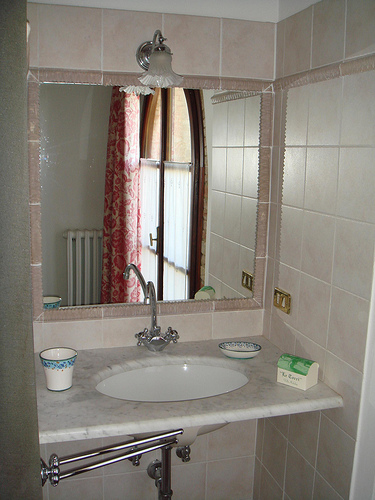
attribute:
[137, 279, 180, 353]
faucet — over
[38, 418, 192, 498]
pipes — silver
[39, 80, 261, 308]
mirror — bathroom, vanity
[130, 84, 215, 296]
arched window — brown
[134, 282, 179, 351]
faucet — nickel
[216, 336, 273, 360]
soap dish — ceramic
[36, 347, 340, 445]
countertop — taupe, white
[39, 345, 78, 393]
cup — blue, white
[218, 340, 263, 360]
bowl — small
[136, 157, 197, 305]
curtain — white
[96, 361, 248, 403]
sink — black, white, marble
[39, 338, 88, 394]
cup — white, blue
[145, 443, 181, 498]
pipes — under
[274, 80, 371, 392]
tile — pink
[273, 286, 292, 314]
gold outlet — electrical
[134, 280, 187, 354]
faucet — silver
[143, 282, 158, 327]
spout — silver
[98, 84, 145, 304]
curtain — red, gold